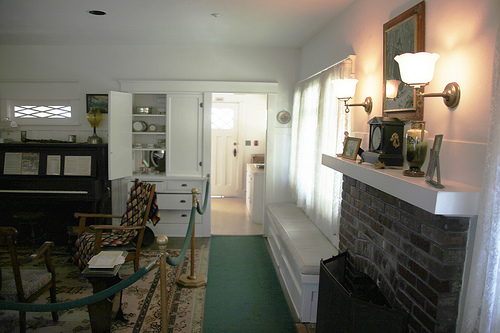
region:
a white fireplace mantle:
[317, 148, 469, 223]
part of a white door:
[205, 105, 239, 194]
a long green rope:
[170, 205, 200, 259]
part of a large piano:
[0, 136, 102, 232]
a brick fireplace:
[315, 184, 456, 329]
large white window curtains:
[288, 65, 351, 230]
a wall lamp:
[396, 50, 467, 107]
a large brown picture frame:
[379, 0, 433, 120]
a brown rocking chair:
[77, 174, 157, 277]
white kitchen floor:
[211, 193, 247, 237]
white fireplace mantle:
[318, 148, 481, 222]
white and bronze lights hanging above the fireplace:
[329, 50, 462, 114]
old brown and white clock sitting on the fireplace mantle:
[366, 114, 405, 169]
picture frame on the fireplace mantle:
[422, 133, 449, 190]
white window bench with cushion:
[261, 198, 341, 324]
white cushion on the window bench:
[263, 197, 343, 275]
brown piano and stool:
[1, 137, 110, 252]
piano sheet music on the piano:
[43, 153, 93, 178]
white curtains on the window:
[286, 57, 351, 242]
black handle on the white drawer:
[178, 181, 188, 187]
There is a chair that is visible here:
[96, 190, 121, 323]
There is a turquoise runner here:
[237, 235, 252, 293]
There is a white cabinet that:
[160, 111, 174, 233]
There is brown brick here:
[371, 217, 418, 319]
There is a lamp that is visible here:
[408, 38, 427, 91]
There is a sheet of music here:
[53, 148, 63, 175]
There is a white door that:
[216, 125, 233, 199]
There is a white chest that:
[266, 223, 307, 331]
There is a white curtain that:
[467, 229, 496, 298]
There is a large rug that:
[61, 279, 68, 296]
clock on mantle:
[356, 100, 419, 175]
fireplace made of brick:
[343, 183, 458, 293]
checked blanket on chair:
[104, 175, 162, 249]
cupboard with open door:
[101, 88, 213, 196]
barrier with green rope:
[153, 169, 204, 331]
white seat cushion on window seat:
[265, 193, 329, 310]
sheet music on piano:
[4, 139, 111, 212]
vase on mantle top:
[403, 113, 429, 180]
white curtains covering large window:
[283, 67, 343, 237]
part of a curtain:
[486, 249, 496, 266]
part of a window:
[311, 187, 323, 212]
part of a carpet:
[191, 285, 198, 301]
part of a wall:
[371, 244, 378, 261]